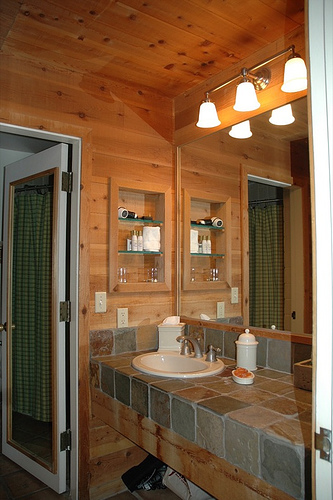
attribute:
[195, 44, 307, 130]
sconce — overhead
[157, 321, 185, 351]
tissue holder — square, porcelaine, white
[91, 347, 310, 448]
counter — tile, rustic, stone tile, gray, stone, tiled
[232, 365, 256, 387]
soap dish — white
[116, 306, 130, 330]
electrical outlet — white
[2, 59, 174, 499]
wall — natural wood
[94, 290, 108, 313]
light switch — white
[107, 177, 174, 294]
shelves — built in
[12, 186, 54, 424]
curtain — green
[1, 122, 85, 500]
door frame — white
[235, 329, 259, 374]
container — white, decorative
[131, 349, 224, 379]
sink — white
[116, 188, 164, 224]
shelf — glass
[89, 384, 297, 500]
base — natural wood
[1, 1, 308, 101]
ceiling — natural wood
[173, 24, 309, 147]
wall — natural wood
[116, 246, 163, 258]
shelf — glass